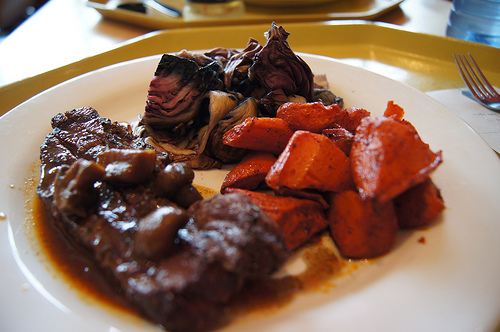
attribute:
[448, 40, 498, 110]
fork — metal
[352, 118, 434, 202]
carrot — orange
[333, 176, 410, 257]
carrot — orange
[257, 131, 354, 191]
carrot — orange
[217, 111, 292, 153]
carrot — orange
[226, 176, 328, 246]
carrot — orange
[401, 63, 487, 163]
plate — nice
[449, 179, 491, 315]
plate — white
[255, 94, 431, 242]
yams — orange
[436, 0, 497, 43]
bottle — blue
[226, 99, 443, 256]
carrots — roasted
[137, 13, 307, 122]
cabbage — purple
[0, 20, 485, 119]
tray — gold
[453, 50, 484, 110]
fork — silver